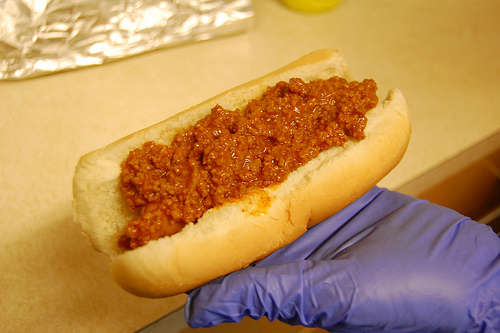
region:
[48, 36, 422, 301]
a chili dog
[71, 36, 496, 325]
a blue gloved hand holding a chili dog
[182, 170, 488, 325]
a blue gloved hand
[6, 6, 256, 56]
aluminum foil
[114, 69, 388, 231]
chili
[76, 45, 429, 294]
cony dog being held by blue gloved hand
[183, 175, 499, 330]
blue plastic glove over hand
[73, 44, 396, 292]
white hot dog bun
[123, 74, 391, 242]
chili beef cony topping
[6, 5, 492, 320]
light colored countertop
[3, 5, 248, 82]
piece of silver foil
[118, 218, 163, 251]
tip of hot dog under cony meat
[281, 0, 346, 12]
edge of yellow cup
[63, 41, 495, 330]
hot dog being served by gloved hand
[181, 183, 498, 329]
blue plastic glove on hand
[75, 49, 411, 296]
hot dog with chili on it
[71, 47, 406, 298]
a golden brown hotdog bun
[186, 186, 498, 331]
blue latex glove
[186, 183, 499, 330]
a gloved left hand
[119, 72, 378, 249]
chili topping on a hotdog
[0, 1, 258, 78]
piece of shiny paper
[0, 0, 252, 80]
sheet of aluminum foil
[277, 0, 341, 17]
bottom of mustard bottle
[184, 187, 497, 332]
a blue rubber glove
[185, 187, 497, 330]
a wrinkled latex glove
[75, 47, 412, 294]
a chili dog being served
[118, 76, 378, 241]
chili on a chili dog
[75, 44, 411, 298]
a golden brown hotdog bun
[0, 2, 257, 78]
shiny piece of aluminum foil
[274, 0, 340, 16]
a bottle of yellow mustard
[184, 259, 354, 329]
a gloved left thumb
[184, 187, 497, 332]
a gloved left hand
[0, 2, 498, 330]
a food counter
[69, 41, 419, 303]
ground meat on hot dog bun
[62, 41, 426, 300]
hot dog bun with ground meat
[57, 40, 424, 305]
seasoned meat on bun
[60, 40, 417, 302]
white bread hot dog bun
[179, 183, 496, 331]
gloved hand holding bun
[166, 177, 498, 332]
hand wearing purple safety glove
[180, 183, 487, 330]
purple safety latex glove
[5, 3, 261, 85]
portion of wrinkled aluminum foil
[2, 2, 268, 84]
aluminum foil on counter top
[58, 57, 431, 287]
hotdog bun filled with chili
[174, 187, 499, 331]
blue rubber glove on a hand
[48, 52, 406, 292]
hotdog bun in someone's hand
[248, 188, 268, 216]
chili stain on the bun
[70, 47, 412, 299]
chili inside of white bun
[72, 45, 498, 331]
gloves hand holding a chili dog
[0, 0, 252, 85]
crumpled shiny silver foil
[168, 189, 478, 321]
blue rubber glove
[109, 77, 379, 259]
chili in the hotodog bun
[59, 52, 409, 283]
bun filled with chili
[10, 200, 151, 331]
shadow on the counter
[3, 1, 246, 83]
aluminum foil on the counter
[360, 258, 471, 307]
light reflection on the glove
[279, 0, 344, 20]
yellow object on the counter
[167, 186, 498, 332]
hand holding a hotdog bun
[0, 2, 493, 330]
counter behind the hotdog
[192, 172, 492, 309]
A glove on a hand.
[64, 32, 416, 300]
A hotdog bun with meat.